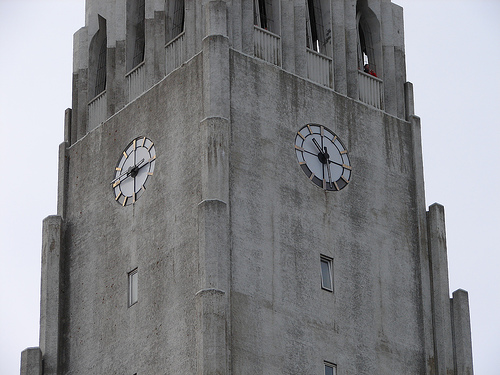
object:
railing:
[161, 31, 188, 76]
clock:
[292, 121, 353, 193]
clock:
[109, 132, 160, 209]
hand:
[132, 157, 144, 170]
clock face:
[291, 120, 354, 194]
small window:
[321, 357, 339, 375]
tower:
[14, 1, 477, 374]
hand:
[108, 171, 129, 188]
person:
[363, 63, 379, 78]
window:
[353, 0, 385, 81]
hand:
[310, 137, 327, 156]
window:
[318, 251, 337, 295]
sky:
[0, 0, 499, 375]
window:
[125, 265, 141, 310]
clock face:
[107, 133, 157, 208]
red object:
[364, 70, 378, 78]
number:
[317, 123, 326, 139]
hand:
[324, 155, 334, 191]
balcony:
[356, 70, 384, 113]